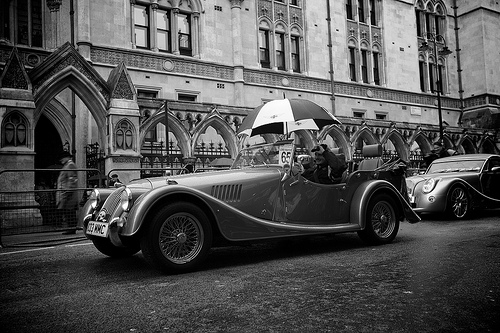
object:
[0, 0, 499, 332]
picture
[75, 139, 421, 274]
car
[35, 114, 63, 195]
doorway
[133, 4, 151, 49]
window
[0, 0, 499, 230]
building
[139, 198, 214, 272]
wheel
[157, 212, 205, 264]
rims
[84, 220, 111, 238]
license plate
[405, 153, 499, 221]
car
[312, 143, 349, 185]
man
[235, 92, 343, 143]
umbrella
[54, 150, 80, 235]
man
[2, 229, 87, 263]
sidewalk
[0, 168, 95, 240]
barricade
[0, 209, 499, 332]
road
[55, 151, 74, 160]
hat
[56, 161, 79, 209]
coat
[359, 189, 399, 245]
wheel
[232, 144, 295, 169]
windshield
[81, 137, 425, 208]
fence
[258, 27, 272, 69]
window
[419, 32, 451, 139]
street lamp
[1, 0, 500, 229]
arches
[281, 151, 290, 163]
65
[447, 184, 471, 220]
wheel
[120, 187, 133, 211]
headlight